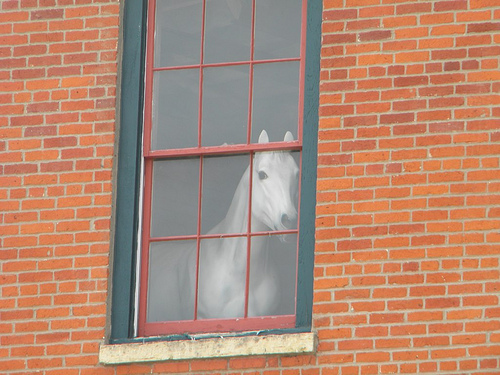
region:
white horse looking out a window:
[186, 130, 299, 325]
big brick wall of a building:
[0, 0, 499, 373]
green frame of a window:
[109, 0, 322, 343]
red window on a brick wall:
[134, 0, 306, 336]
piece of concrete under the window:
[98, 333, 313, 365]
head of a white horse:
[248, 131, 297, 235]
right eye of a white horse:
[258, 171, 267, 179]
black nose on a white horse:
[282, 214, 296, 227]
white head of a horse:
[248, 130, 298, 234]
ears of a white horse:
[260, 130, 294, 142]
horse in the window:
[120, 93, 321, 340]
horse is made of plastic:
[135, 107, 316, 330]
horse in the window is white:
[163, 119, 305, 369]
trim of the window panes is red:
[139, 2, 304, 341]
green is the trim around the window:
[120, 0, 328, 334]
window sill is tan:
[89, 335, 330, 360]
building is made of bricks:
[369, 140, 495, 333]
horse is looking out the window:
[247, 121, 314, 248]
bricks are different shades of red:
[369, 61, 498, 368]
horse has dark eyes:
[250, 166, 304, 186]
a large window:
[136, 5, 304, 337]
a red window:
[146, 0, 294, 332]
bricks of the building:
[323, 5, 498, 365]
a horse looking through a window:
[149, 136, 296, 330]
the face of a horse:
[246, 135, 300, 237]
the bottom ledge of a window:
[96, 335, 322, 362]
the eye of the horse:
[255, 168, 267, 178]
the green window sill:
[119, 23, 136, 340]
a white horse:
[150, 129, 300, 312]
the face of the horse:
[249, 133, 306, 245]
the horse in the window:
[155, 97, 303, 327]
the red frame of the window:
[148, 0, 303, 325]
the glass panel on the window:
[155, 65, 197, 153]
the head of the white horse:
[221, 117, 306, 270]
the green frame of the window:
[106, 5, 146, 347]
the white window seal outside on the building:
[95, 328, 326, 360]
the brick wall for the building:
[1, 2, 98, 362]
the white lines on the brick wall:
[1, 0, 89, 336]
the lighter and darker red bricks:
[321, 0, 391, 68]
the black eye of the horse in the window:
[249, 166, 271, 185]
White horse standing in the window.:
[233, 129, 310, 226]